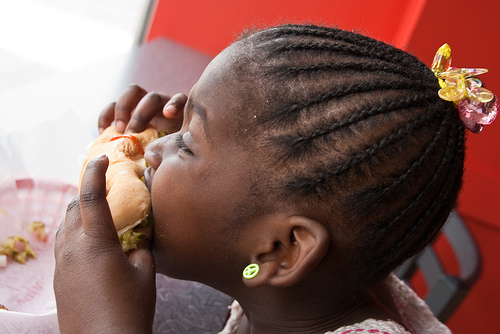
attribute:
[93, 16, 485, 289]
girl — little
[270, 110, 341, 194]
hair — black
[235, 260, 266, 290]
earring — tiny, yellow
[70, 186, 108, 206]
knuckles — small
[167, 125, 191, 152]
eyelash — long, luxurious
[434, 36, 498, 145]
ribbon — pink, yellow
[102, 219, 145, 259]
relish — green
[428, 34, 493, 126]
clip — colorful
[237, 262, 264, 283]
earring — peace sign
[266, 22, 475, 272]
hair — brown, corn row style